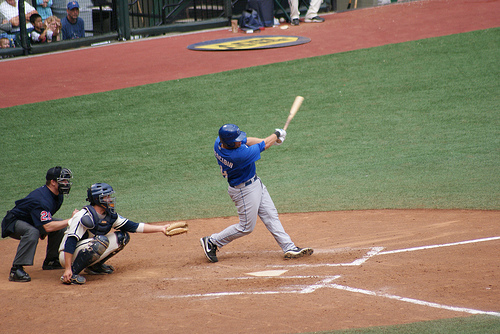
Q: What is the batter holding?
A: Bat.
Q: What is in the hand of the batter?
A: Bat.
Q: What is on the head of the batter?
A: Helmet.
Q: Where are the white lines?
A: On the ground.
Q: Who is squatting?
A: The catcher.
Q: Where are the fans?
A: Behind the fence.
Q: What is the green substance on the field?
A: Grass.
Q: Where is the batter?
A: Beside home base.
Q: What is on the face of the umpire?
A: A face mask.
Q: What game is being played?
A: Baseball.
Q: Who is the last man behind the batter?
A: The umpire.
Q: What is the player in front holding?
A: A bat.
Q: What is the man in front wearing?
A: A baseball uniform.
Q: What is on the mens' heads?
A: Helmets.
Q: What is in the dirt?
A: White lines.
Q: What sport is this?
A: Baseball.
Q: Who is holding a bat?
A: Batter.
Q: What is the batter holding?
A: A bat.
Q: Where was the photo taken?
A: Baseball field.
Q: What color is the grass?
A: Green.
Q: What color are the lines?
A: White.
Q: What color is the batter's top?
A: Blue.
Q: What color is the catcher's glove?
A: Brown.